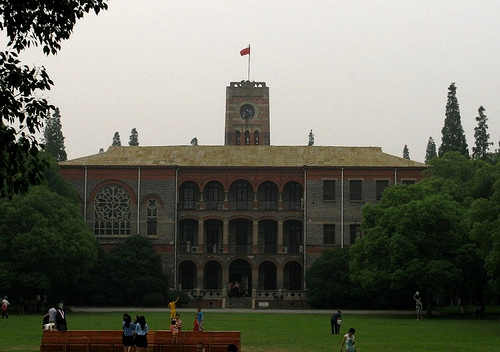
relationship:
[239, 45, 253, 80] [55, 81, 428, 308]
flag on top of building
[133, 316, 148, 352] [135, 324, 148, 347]
girl wearing uniform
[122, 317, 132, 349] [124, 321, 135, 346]
girl wearing uniform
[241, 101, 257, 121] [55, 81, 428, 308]
clock on building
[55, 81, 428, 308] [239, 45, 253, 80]
building has flag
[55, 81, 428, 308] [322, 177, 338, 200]
building has window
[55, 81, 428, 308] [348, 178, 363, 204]
building has window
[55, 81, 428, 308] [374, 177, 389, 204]
building has window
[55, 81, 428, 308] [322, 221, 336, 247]
building has window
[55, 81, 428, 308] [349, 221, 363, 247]
building has window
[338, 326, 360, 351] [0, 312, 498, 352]
person walking on grass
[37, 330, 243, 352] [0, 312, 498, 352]
bench on grass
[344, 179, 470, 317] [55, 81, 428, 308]
tree in front of building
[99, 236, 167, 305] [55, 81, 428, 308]
tree in front of building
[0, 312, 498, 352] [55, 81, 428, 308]
grass in front of building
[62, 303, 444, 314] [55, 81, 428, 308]
side walk in front of building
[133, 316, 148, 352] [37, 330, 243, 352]
girl behind bench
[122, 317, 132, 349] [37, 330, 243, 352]
girl behind bench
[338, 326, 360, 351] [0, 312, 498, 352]
person in grass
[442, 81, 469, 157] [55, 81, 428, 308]
tree behind building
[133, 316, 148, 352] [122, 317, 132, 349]
girl standing by girl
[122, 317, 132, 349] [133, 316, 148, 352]
girl standing by girl